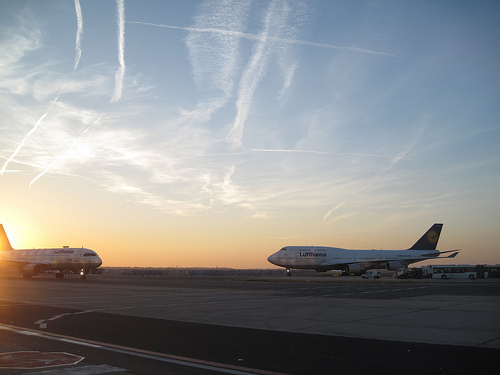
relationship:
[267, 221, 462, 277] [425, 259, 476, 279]
airliner next to a bus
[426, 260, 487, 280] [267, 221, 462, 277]
bus next to a airliner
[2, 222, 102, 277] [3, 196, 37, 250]
airplane obstructing a sunrise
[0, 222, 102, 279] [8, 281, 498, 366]
airplane on a runway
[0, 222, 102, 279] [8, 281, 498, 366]
airplane on runway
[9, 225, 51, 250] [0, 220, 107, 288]
light behind plane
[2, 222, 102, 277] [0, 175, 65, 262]
airplane tower sun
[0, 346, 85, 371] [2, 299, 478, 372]
painting on cement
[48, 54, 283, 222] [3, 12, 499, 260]
clouds across sky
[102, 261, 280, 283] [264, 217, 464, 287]
trees near planes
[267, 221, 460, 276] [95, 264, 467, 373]
airliner on runway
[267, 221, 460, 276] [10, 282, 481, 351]
airliner on runway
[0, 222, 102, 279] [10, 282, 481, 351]
airplane on runway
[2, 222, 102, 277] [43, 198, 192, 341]
airplane obstructing sunset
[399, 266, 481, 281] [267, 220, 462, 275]
shuttle behind airplane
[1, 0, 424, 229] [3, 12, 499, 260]
smoke in sky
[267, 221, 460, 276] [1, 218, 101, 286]
airliner facing airplane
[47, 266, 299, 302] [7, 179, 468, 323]
lights glowing under planes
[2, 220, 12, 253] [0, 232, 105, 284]
tail of plane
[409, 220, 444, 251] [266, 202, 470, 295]
tail of plane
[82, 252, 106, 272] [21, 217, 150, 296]
nose of plane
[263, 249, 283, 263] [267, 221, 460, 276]
nose of airliner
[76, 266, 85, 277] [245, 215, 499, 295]
front wheels of plane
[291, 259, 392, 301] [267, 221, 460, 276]
wheels on airliner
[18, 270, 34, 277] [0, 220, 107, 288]
back wheels on plane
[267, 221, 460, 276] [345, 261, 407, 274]
airliner has side engines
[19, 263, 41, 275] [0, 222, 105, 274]
engine on plane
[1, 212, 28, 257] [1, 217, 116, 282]
sun behind airplane